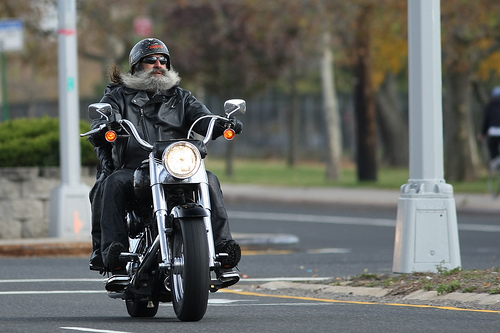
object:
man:
[86, 36, 244, 274]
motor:
[78, 96, 247, 323]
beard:
[117, 67, 181, 92]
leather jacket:
[86, 86, 237, 167]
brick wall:
[1, 180, 49, 250]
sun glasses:
[140, 53, 167, 66]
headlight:
[160, 140, 202, 181]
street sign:
[2, 16, 30, 55]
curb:
[1, 233, 298, 256]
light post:
[47, 0, 96, 245]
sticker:
[59, 29, 75, 37]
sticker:
[62, 77, 82, 93]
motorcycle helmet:
[129, 36, 171, 75]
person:
[88, 68, 124, 272]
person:
[479, 84, 497, 169]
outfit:
[485, 97, 498, 160]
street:
[1, 188, 496, 329]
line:
[218, 287, 498, 315]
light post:
[391, 0, 465, 275]